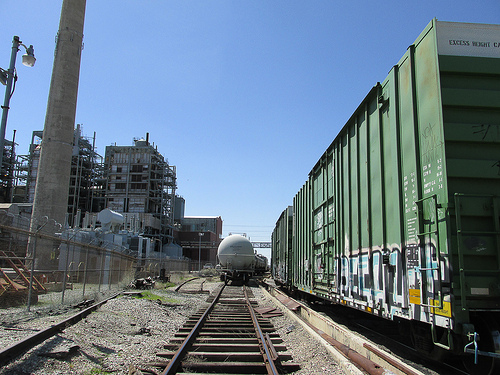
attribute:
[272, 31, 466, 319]
train — green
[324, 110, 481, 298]
train — green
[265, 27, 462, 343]
train — green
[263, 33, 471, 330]
train — green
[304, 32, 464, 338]
train — green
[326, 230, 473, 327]
train — side, Graffiti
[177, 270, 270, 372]
tracks — Railroad, gravel road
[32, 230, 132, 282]
fence — Barbed wire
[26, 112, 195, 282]
building —  under construction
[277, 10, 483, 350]
cars — Green train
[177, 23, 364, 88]
sky — no clouds, Blue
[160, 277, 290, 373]
railroad tracks — Gravel 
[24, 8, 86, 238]
pole — Tall streetlight 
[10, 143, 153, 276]
equipment — work yardt 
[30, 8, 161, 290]
pillar — work yardt , Concrete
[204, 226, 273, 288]
cart — rounded train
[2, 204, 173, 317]
fence — barbed wire, chain link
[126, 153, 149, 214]
stories — multiple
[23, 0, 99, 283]
pole — large, concrete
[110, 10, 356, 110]
sky — with no clouds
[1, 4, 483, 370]
scene — during the day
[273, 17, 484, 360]
train — green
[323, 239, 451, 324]
art — graffiti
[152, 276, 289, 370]
train track — in center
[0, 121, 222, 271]
buildings — a group, rundown looking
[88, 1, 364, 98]
sky — clear and visible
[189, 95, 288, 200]
sky — clear and visible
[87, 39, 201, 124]
sky — clear and visible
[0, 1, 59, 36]
sky — clear and visible